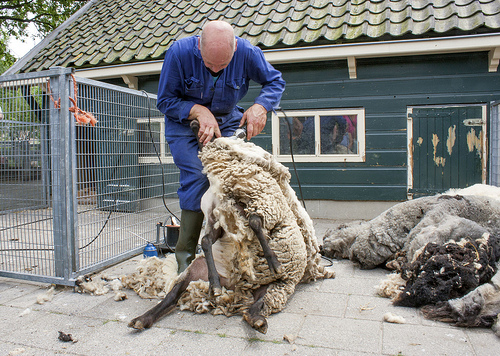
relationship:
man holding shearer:
[156, 21, 285, 276] [213, 121, 260, 145]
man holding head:
[156, 21, 285, 276] [197, 130, 282, 182]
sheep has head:
[121, 135, 324, 341] [197, 130, 282, 182]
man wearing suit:
[153, 17, 288, 276] [155, 36, 285, 208]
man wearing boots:
[156, 21, 285, 276] [163, 203, 208, 293]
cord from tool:
[278, 107, 307, 211] [235, 112, 268, 139]